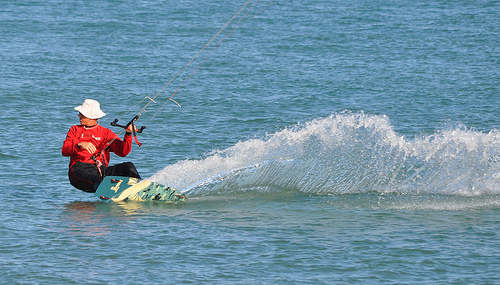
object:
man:
[65, 94, 142, 192]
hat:
[73, 98, 106, 119]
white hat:
[74, 100, 105, 121]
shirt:
[61, 123, 134, 168]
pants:
[69, 160, 143, 193]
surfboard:
[94, 172, 184, 202]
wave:
[144, 107, 499, 214]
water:
[2, 1, 500, 284]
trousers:
[68, 163, 142, 192]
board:
[93, 175, 188, 206]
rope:
[137, 1, 249, 115]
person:
[62, 99, 142, 192]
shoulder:
[66, 124, 84, 137]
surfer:
[61, 99, 141, 193]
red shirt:
[61, 124, 132, 165]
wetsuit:
[61, 124, 141, 192]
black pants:
[68, 162, 141, 194]